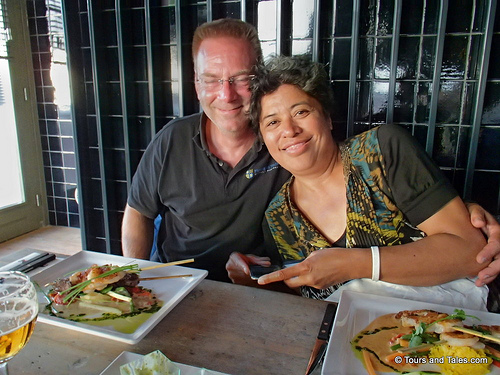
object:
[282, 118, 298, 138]
nose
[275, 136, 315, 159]
mouth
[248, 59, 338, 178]
head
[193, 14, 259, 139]
head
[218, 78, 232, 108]
nose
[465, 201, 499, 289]
hand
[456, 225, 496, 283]
elbow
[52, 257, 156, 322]
vegetables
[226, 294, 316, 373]
table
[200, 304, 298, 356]
table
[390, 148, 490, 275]
arm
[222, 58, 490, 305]
someone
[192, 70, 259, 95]
glasses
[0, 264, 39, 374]
glass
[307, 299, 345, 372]
knife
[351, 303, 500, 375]
food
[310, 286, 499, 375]
plate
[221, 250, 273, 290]
hand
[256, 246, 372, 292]
hand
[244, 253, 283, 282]
cell phone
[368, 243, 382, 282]
band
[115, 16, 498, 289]
man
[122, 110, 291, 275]
shirt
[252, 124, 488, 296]
top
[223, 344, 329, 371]
tabletop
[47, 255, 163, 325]
food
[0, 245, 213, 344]
plate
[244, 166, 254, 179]
logo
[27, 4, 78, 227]
tile